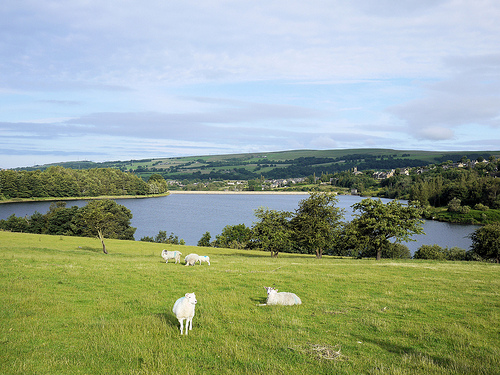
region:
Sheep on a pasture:
[161, 250, 211, 267]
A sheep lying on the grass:
[261, 286, 300, 304]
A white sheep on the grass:
[261, 287, 300, 305]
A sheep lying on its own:
[260, 285, 300, 307]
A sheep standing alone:
[172, 290, 199, 335]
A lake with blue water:
[166, 204, 222, 224]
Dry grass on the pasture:
[316, 346, 336, 357]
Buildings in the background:
[277, 180, 289, 185]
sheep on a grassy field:
[48, 227, 305, 374]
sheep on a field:
[103, 248, 310, 340]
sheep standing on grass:
[163, 287, 203, 331]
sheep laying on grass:
[258, 282, 303, 317]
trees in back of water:
[25, 158, 176, 198]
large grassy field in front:
[40, 250, 136, 341]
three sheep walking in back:
[155, 245, 211, 270]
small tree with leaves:
[67, 195, 144, 265]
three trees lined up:
[244, 199, 437, 267]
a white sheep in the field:
[171, 292, 198, 337]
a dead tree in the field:
[94, 222, 109, 257]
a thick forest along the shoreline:
[1, 167, 169, 199]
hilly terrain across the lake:
[138, 142, 346, 177]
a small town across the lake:
[228, 157, 496, 191]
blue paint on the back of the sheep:
[201, 252, 208, 260]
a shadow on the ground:
[346, 329, 462, 373]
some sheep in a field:
[128, 227, 348, 355]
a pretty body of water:
[23, 172, 495, 280]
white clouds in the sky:
[62, 32, 464, 153]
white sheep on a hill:
[147, 236, 330, 360]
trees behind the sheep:
[52, 178, 428, 283]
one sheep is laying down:
[252, 280, 334, 328]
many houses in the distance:
[215, 154, 498, 194]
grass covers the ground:
[5, 228, 495, 362]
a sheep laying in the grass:
[242, 276, 351, 323]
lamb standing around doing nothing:
[171, 290, 196, 332]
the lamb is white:
[170, 290, 195, 332]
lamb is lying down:
[260, 285, 300, 302]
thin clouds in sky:
[0, 0, 495, 167]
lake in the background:
[0, 192, 482, 257]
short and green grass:
[1, 229, 498, 372]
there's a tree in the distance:
[351, 200, 422, 260]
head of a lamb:
[185, 293, 195, 301]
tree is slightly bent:
[74, 199, 130, 254]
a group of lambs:
[161, 245, 209, 265]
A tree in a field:
[346, 197, 420, 257]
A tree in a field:
[255, 208, 293, 262]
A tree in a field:
[300, 196, 331, 251]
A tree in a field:
[230, 225, 245, 254]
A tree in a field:
[213, 233, 228, 248]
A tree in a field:
[201, 233, 212, 248]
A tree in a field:
[85, 207, 107, 260]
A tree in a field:
[90, 197, 136, 241]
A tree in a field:
[51, 209, 80, 231]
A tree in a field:
[22, 212, 48, 239]